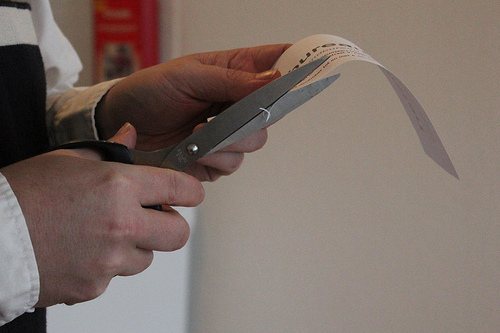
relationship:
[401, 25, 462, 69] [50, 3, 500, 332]
color of walls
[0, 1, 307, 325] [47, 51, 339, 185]
man holding scissors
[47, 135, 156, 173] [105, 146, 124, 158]
handle of scsors black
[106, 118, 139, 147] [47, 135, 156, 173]
thumb through handle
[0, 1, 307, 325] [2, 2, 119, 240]
man wearing shirt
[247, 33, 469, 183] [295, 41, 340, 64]
paper has black text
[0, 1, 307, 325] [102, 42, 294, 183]
man holding paper in hands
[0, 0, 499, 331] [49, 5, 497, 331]
picture taken indoors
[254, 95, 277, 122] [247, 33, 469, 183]
sliver of paper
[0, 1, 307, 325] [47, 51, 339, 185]
person holding scissors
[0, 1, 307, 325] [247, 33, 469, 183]
person holding paper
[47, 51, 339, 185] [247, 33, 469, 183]
scissors are cutting paper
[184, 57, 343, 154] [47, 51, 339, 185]
two blades on pair of scissors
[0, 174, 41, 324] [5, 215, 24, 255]
cuff on shirt white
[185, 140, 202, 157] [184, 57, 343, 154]
screw holds two blades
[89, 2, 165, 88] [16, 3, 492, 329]
blury red object in background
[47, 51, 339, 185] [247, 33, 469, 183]
scissors used for cutting paper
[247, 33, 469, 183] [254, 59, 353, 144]
paper being cut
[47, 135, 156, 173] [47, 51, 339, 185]
handle on scissors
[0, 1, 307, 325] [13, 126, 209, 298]
person's right hand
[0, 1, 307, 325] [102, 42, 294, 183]
person's left hands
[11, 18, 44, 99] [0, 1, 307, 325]
black and white shirt on person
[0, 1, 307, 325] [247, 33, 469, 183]
person cutting a paper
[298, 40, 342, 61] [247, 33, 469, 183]
black text on paper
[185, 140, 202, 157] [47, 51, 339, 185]
silver screw on scissors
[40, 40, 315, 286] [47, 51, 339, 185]
hands holding scissors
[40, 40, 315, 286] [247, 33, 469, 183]
hands cutting paper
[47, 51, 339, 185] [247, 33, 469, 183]
scissors cutting paper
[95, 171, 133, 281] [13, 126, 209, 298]
knuckles on a hand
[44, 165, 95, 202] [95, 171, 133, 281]
caucasian hand knuckles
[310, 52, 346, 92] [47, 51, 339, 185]
tip of scissors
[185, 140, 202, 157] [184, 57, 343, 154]
screw that holds blades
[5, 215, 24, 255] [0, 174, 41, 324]
white fabric cuff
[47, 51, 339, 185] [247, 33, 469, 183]
scissors cut paper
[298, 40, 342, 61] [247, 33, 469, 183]
lettering on paper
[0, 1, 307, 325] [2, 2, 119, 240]
person wears a white shirt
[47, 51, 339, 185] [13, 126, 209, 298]
scissors are on right hand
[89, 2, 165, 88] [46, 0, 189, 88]
red object on wall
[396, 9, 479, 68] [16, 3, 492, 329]
beige wall in background